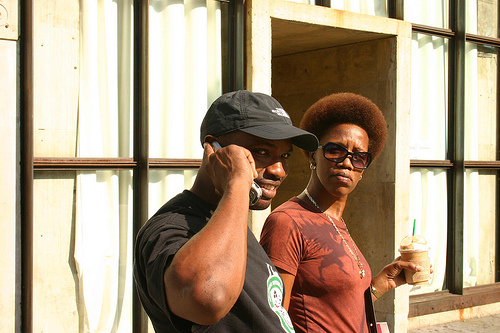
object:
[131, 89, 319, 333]
person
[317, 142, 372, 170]
sunglasses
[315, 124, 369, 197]
face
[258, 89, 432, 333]
afro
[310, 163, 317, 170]
earring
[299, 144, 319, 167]
right ear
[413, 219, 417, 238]
straw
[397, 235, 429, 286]
drink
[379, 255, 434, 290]
hand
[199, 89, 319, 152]
hat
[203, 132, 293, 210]
head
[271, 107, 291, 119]
logo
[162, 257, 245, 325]
right elbow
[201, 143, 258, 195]
right hand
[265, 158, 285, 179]
nose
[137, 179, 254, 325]
arm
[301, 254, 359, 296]
breast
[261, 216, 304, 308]
arm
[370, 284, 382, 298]
wrist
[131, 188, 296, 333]
shirt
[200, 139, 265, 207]
cellphone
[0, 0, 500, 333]
day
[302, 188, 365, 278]
necklace